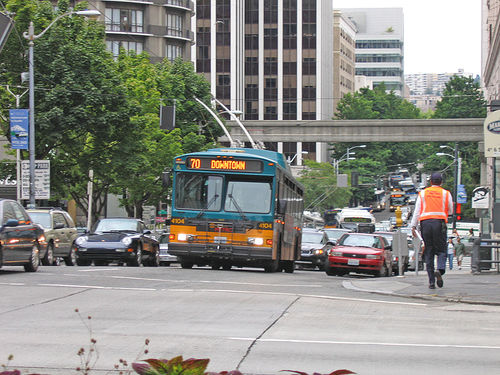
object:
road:
[3, 264, 499, 372]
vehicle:
[326, 227, 389, 275]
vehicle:
[29, 207, 79, 270]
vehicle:
[298, 227, 330, 273]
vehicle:
[1, 198, 49, 278]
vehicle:
[387, 190, 409, 212]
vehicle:
[335, 206, 378, 230]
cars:
[74, 218, 152, 264]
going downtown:
[3, 141, 413, 371]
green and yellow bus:
[167, 145, 307, 273]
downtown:
[3, 6, 493, 374]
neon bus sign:
[188, 155, 247, 172]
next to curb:
[343, 230, 419, 296]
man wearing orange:
[410, 172, 455, 294]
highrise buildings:
[105, 1, 500, 146]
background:
[194, 9, 499, 117]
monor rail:
[214, 117, 486, 145]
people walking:
[409, 172, 475, 292]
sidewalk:
[389, 230, 495, 294]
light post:
[27, 23, 39, 207]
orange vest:
[416, 184, 450, 219]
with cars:
[3, 120, 418, 280]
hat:
[430, 171, 443, 181]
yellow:
[393, 210, 401, 224]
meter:
[395, 205, 405, 227]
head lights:
[251, 236, 262, 245]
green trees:
[3, 1, 165, 219]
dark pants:
[419, 221, 448, 281]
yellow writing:
[169, 218, 185, 226]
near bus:
[305, 184, 392, 278]